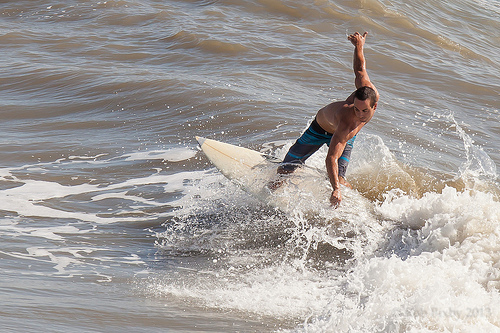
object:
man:
[194, 32, 379, 223]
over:
[261, 130, 356, 211]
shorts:
[277, 120, 359, 178]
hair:
[353, 86, 378, 108]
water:
[0, 2, 498, 330]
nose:
[359, 111, 364, 118]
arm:
[347, 32, 375, 88]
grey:
[51, 34, 183, 109]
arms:
[327, 122, 357, 209]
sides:
[285, 99, 343, 156]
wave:
[244, 116, 496, 331]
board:
[193, 136, 373, 235]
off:
[318, 113, 368, 139]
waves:
[0, 0, 497, 333]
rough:
[360, 183, 499, 323]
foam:
[6, 146, 209, 280]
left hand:
[348, 32, 368, 47]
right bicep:
[334, 130, 350, 157]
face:
[353, 98, 373, 122]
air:
[390, 102, 486, 179]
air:
[156, 176, 346, 285]